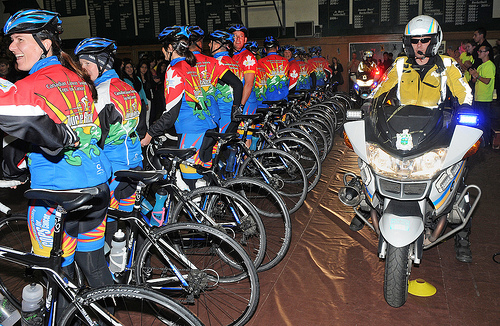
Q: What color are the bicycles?
A: Black.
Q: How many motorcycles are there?
A: One.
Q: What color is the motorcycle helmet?
A: White.